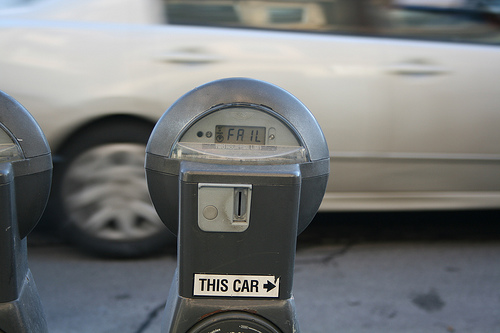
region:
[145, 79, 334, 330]
a grey parking meter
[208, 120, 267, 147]
screen reading FAIL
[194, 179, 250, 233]
a coin insertion slot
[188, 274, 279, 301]
sticker that reads THIS CAR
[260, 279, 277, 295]
an arrow pointing to right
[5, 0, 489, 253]
a blurry silver car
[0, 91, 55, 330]
a grey parking meter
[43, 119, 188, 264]
a car rear passenger tire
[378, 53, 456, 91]
car front passenger side handle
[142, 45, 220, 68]
car rear passenger side handle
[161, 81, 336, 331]
a parking meter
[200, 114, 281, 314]
a parking meter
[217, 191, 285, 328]
a parking meter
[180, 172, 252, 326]
a parking meter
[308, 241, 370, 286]
small road crack visible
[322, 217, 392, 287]
small road crack visible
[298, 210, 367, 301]
small road crack visible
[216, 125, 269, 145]
The meter says fail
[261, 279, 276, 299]
An arrow on the sticker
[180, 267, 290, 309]
A sticker on the meter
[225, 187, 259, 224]
A coin slot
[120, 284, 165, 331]
A crack in the road.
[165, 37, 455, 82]
The car door handles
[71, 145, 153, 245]
The rim for the tire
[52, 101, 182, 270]
The tire for the car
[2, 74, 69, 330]
Another parking meter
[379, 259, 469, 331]
Spots on the road.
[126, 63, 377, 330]
parking meter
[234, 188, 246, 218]
skinny slot for coins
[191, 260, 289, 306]
black and white sticker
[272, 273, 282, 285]
tear in the corner of the sticker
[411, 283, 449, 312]
dark spot on the ground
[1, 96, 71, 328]
half of a parking meter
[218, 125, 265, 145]
digital screen reads "fail"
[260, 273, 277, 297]
black arrow pointing to the right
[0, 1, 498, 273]
car that is in motion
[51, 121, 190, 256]
back tire